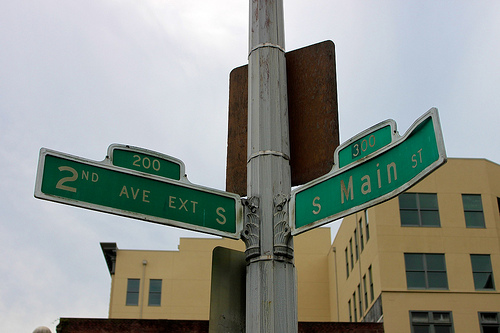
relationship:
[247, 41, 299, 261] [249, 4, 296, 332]
brackets on a street pole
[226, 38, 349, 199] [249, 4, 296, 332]
street sign attached to street pole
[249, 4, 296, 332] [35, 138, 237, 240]
street pole with sign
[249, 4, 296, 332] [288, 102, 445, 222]
street pole with sign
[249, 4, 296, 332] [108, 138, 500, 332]
street pole in front of building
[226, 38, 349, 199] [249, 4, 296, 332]
street sign on street pole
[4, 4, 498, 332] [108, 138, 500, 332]
sky above building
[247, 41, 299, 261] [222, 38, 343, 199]
brackets holding street sign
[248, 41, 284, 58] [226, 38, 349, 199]
top bracket on street sign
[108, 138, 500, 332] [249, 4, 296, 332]
building behind street pole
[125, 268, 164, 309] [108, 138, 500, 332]
windows on building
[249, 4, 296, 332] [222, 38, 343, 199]
street pole with attached street sign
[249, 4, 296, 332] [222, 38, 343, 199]
street pole with street sign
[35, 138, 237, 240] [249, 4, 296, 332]
sign on street pole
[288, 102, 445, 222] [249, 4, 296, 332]
sign on street pole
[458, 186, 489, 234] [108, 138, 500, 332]
window on building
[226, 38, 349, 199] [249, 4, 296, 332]
street sign hanging on street pole